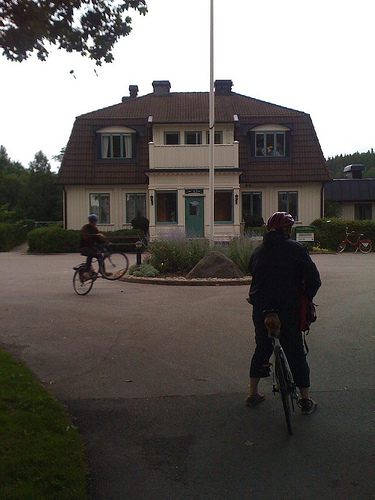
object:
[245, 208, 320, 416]
woman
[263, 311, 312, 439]
bike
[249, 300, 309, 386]
pants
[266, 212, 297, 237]
helmet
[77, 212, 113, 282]
boy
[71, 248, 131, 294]
bike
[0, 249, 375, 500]
sidewalk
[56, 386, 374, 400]
crack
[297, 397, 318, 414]
shoes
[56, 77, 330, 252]
house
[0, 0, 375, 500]
background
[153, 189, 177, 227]
window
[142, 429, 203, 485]
stain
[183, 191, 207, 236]
door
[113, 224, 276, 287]
flower bed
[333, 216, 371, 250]
bike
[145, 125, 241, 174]
balcony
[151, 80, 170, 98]
chimneys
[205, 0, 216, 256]
pole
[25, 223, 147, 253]
bush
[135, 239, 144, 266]
sign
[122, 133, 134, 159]
curtains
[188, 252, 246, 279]
rock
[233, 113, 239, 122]
light